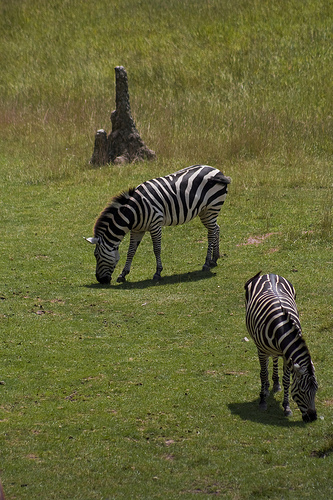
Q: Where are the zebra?
A: In a field.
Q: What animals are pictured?
A: Zebra.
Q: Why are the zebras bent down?
A: The are grazing.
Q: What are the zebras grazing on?
A: Grass.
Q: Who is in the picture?
A: No one is in the picture.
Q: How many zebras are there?
A: Two.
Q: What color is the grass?
A: Green.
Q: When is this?
A: Daytime.